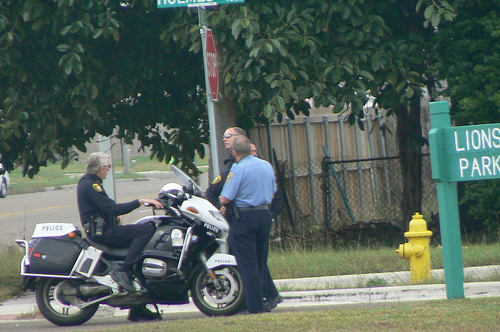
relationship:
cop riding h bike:
[77, 150, 165, 317] [11, 165, 245, 327]